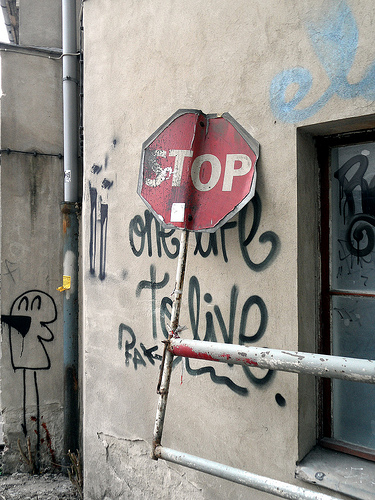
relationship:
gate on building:
[320, 130, 375, 465] [83, 1, 375, 500]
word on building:
[126, 203, 188, 263] [83, 1, 375, 500]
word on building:
[190, 182, 284, 272] [83, 1, 375, 500]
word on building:
[132, 261, 179, 341] [83, 1, 375, 500]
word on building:
[115, 316, 161, 372] [83, 1, 375, 500]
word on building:
[181, 271, 287, 396] [83, 1, 375, 500]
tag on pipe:
[56, 262, 73, 294] [43, 68, 108, 375]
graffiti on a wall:
[3, 284, 59, 457] [1, 1, 82, 471]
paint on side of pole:
[170, 345, 258, 369] [170, 337, 374, 384]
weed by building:
[17, 435, 55, 473] [83, 1, 375, 500]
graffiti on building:
[90, 163, 285, 405] [83, 1, 375, 500]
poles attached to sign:
[139, 229, 374, 499] [132, 101, 263, 241]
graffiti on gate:
[329, 154, 372, 255] [320, 130, 375, 465]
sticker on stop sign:
[170, 202, 185, 223] [136, 108, 260, 444]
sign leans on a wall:
[132, 101, 263, 241] [89, 12, 279, 106]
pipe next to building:
[61, 68, 78, 375] [24, 145, 291, 489]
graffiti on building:
[90, 163, 285, 405] [75, 1, 373, 499]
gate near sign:
[320, 130, 375, 465] [123, 95, 278, 238]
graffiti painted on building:
[90, 163, 285, 405] [83, 1, 375, 500]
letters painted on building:
[269, 0, 373, 124] [83, 1, 375, 500]